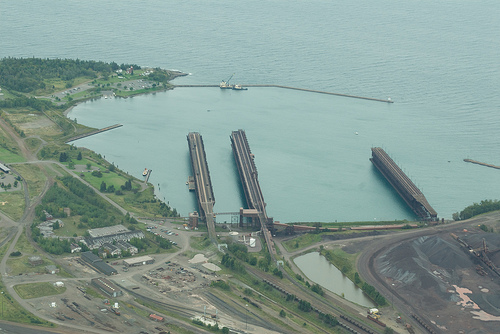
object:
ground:
[0, 247, 224, 334]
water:
[290, 244, 376, 306]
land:
[2, 222, 496, 332]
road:
[219, 240, 381, 332]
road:
[364, 219, 457, 331]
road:
[3, 165, 46, 326]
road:
[108, 233, 195, 282]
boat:
[220, 73, 248, 90]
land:
[24, 124, 73, 140]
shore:
[59, 90, 107, 117]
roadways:
[184, 207, 304, 294]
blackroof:
[81, 252, 119, 276]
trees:
[37, 177, 165, 254]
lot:
[134, 210, 206, 260]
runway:
[169, 79, 394, 104]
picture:
[0, 2, 498, 331]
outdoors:
[0, 2, 499, 332]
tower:
[162, 203, 217, 246]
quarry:
[370, 228, 500, 334]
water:
[2, 1, 499, 222]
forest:
[1, 55, 159, 92]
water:
[132, 89, 483, 189]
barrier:
[173, 84, 392, 102]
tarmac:
[356, 216, 497, 331]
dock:
[365, 143, 441, 219]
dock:
[229, 129, 267, 231]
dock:
[186, 132, 218, 223]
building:
[70, 224, 146, 258]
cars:
[145, 224, 200, 248]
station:
[179, 80, 397, 116]